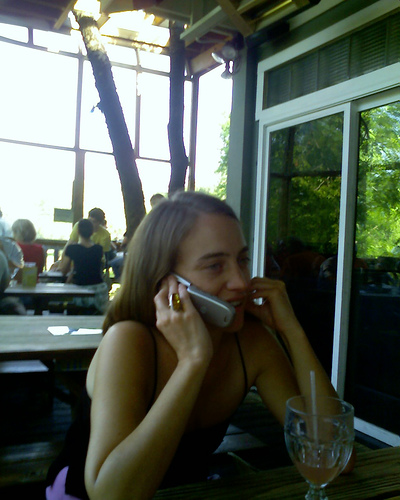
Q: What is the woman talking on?
A: A phone.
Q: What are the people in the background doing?
A: Dining.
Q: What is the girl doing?
A: Talking on a cell phone.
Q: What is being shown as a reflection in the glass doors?
A: Trees.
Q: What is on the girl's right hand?
A: A large ring.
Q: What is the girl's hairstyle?
A: Long and straight.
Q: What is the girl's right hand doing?
A: Holding the cell phone.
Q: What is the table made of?
A: Wood.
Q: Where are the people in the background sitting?
A: At a table.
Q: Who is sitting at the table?
A: A lady.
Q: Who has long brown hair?
A: The girl.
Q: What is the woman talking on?
A: Cell phone.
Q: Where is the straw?
A: In a glass.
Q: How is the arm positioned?
A: Bent.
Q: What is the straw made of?
A: Plastic.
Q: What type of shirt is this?
A: Thin strapped.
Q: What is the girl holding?
A: A phone.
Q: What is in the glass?
A: A straw.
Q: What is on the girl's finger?
A: A ring.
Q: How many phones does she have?
A: One.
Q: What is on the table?
A: A glass.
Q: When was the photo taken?
A: Daytime.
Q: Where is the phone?
A: In her hand.